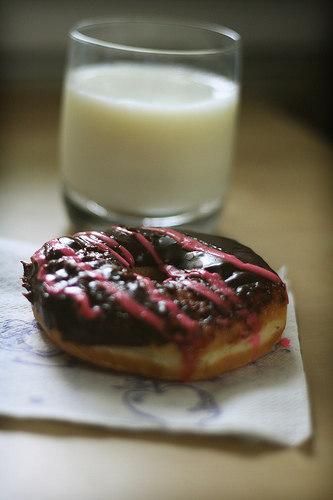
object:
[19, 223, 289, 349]
frosting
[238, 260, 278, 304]
chocolate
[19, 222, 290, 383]
donut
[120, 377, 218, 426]
apple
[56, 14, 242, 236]
glass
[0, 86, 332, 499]
table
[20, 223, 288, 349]
icing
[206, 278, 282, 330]
side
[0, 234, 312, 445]
napkin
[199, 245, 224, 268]
light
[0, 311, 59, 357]
pattern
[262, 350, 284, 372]
crumb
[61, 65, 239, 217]
milk